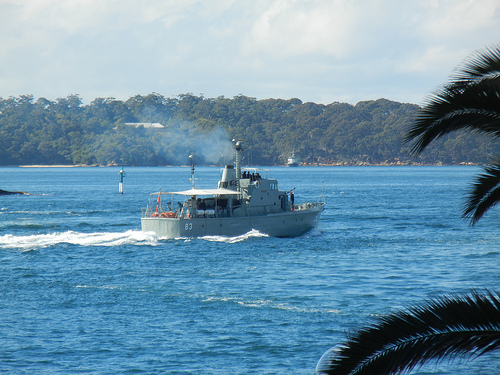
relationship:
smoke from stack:
[166, 129, 221, 154] [213, 162, 248, 175]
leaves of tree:
[413, 130, 452, 149] [314, 296, 496, 373]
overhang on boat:
[167, 188, 241, 196] [140, 216, 328, 237]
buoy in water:
[108, 168, 130, 196] [84, 277, 207, 300]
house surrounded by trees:
[277, 148, 303, 167] [215, 116, 335, 145]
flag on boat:
[182, 177, 201, 191] [140, 216, 328, 237]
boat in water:
[140, 216, 328, 237] [84, 277, 207, 300]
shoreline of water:
[327, 161, 361, 171] [84, 277, 207, 300]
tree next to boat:
[314, 296, 496, 373] [140, 216, 328, 237]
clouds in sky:
[48, 8, 126, 35] [371, 35, 398, 54]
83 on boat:
[180, 221, 198, 236] [140, 216, 328, 237]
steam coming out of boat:
[130, 99, 166, 134] [140, 216, 328, 237]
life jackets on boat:
[142, 211, 184, 217] [140, 216, 328, 237]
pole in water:
[191, 163, 205, 180] [84, 277, 207, 300]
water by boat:
[84, 277, 207, 300] [140, 216, 328, 237]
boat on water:
[140, 216, 328, 237] [84, 277, 207, 300]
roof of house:
[278, 147, 305, 157] [277, 148, 303, 167]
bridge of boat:
[201, 201, 246, 213] [140, 216, 328, 237]